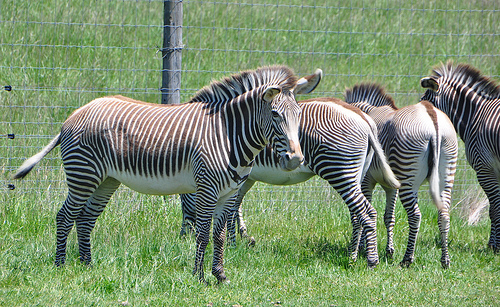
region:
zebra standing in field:
[10, 55, 322, 282]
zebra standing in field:
[198, 89, 400, 272]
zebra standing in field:
[331, 75, 470, 270]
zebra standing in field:
[419, 54, 499, 261]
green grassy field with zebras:
[8, 0, 498, 300]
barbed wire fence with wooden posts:
[8, 3, 498, 206]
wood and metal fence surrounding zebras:
[3, 2, 497, 214]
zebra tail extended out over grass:
[9, 128, 73, 183]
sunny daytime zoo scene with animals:
[6, 5, 496, 305]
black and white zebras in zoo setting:
[21, 49, 499, 284]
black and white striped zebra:
[54, 72, 293, 284]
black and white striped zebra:
[307, 98, 389, 260]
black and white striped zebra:
[361, 87, 472, 278]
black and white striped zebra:
[428, 58, 498, 186]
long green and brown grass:
[28, 14, 106, 66]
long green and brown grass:
[111, 226, 171, 275]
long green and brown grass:
[260, 213, 307, 247]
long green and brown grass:
[258, 239, 319, 284]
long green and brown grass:
[217, 10, 303, 47]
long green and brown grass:
[340, 8, 410, 52]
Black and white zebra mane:
[186, 62, 296, 104]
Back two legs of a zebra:
[51, 143, 123, 270]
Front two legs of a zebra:
[190, 158, 244, 283]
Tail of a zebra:
[9, 125, 63, 183]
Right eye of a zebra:
[268, 105, 282, 121]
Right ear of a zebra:
[260, 81, 285, 103]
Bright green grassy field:
[260, 274, 421, 299]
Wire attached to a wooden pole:
[160, 0, 182, 102]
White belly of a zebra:
[107, 176, 197, 197]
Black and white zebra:
[7, 60, 307, 285]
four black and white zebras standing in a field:
[32, 25, 496, 269]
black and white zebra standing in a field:
[50, 42, 303, 271]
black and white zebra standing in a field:
[267, 78, 395, 265]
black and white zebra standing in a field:
[359, 64, 457, 266]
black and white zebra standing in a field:
[427, 55, 497, 248]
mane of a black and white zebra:
[177, 50, 310, 118]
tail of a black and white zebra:
[9, 107, 74, 204]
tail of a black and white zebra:
[368, 127, 409, 205]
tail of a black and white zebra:
[417, 104, 457, 217]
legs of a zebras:
[334, 189, 480, 276]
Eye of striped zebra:
[270, 110, 283, 122]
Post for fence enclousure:
[162, 0, 188, 100]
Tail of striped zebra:
[364, 120, 404, 192]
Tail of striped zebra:
[431, 125, 448, 215]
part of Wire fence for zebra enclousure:
[8, 33, 117, 86]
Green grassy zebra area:
[271, 247, 320, 294]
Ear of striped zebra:
[416, 73, 440, 90]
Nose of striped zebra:
[279, 147, 314, 162]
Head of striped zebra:
[248, 84, 308, 177]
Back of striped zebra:
[125, 104, 203, 142]